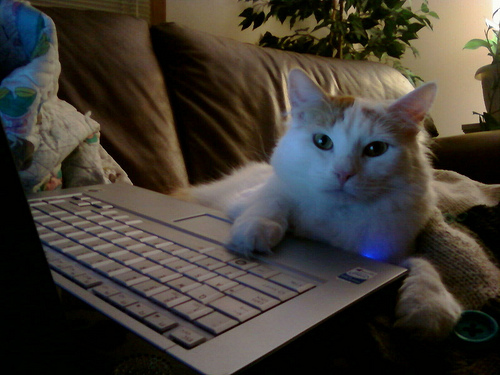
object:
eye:
[312, 133, 334, 151]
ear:
[386, 81, 438, 137]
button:
[453, 310, 499, 342]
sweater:
[403, 169, 500, 375]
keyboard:
[27, 192, 317, 350]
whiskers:
[357, 187, 420, 195]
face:
[298, 101, 407, 204]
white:
[288, 165, 322, 186]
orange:
[309, 94, 355, 127]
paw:
[226, 233, 283, 257]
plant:
[458, 6, 500, 65]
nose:
[331, 167, 358, 185]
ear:
[288, 67, 335, 119]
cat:
[169, 68, 463, 338]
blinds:
[35, 1, 153, 15]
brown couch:
[30, 3, 499, 266]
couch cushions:
[28, 0, 191, 197]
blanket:
[0, 0, 133, 194]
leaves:
[236, 0, 440, 87]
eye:
[362, 140, 389, 157]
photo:
[0, 0, 500, 375]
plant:
[236, 0, 443, 87]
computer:
[0, 119, 410, 374]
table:
[460, 111, 500, 134]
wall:
[161, 0, 500, 138]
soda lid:
[451, 309, 500, 343]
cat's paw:
[396, 283, 461, 335]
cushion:
[150, 20, 438, 186]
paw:
[393, 296, 464, 335]